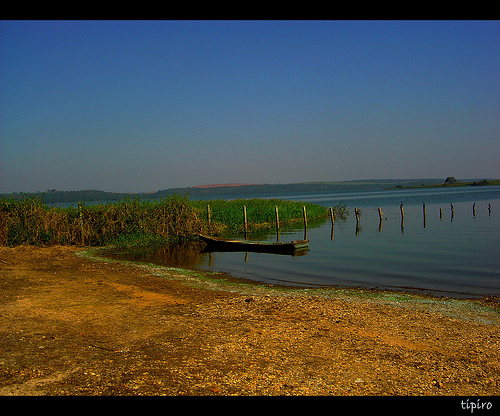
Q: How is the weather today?
A: It is clear.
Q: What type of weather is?
A: It is clear.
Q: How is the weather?
A: It is clear.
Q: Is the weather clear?
A: Yes, it is clear.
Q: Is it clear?
A: Yes, it is clear.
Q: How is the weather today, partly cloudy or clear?
A: It is clear.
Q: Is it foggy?
A: No, it is clear.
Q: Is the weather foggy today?
A: No, it is clear.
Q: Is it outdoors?
A: Yes, it is outdoors.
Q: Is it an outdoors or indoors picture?
A: It is outdoors.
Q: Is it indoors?
A: No, it is outdoors.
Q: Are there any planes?
A: No, there are no planes.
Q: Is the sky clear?
A: Yes, the sky is clear.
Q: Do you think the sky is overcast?
A: No, the sky is clear.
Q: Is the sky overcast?
A: No, the sky is clear.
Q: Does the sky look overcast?
A: No, the sky is clear.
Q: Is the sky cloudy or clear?
A: The sky is clear.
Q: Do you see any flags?
A: No, there are no flags.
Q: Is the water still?
A: Yes, the water is still.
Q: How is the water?
A: The water is still.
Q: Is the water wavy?
A: No, the water is still.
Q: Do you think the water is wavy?
A: No, the water is still.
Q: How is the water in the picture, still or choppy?
A: The water is still.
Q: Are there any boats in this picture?
A: Yes, there is a boat.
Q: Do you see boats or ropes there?
A: Yes, there is a boat.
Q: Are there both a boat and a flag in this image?
A: No, there is a boat but no flags.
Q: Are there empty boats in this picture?
A: Yes, there is an empty boat.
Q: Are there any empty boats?
A: Yes, there is an empty boat.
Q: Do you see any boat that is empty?
A: Yes, there is a boat that is empty.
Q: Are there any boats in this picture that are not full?
A: Yes, there is a empty boat.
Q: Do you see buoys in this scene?
A: No, there are no buoys.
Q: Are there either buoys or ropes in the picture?
A: No, there are no buoys or ropes.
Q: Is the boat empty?
A: Yes, the boat is empty.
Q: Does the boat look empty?
A: Yes, the boat is empty.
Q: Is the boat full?
A: No, the boat is empty.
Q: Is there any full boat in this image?
A: No, there is a boat but it is empty.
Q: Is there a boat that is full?
A: No, there is a boat but it is empty.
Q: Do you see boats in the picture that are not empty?
A: No, there is a boat but it is empty.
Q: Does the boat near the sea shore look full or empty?
A: The boat is empty.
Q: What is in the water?
A: The boat is in the water.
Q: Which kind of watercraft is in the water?
A: The watercraft is a boat.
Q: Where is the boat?
A: The boat is in the water.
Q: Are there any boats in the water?
A: Yes, there is a boat in the water.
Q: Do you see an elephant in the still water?
A: No, there is a boat in the water.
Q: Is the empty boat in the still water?
A: Yes, the boat is in the water.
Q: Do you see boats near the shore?
A: Yes, there is a boat near the shore.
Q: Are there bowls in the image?
A: No, there are no bowls.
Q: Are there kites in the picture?
A: No, there are no kites.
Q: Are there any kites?
A: No, there are no kites.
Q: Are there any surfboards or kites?
A: No, there are no kites or surfboards.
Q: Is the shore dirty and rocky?
A: Yes, the shore is dirty and rocky.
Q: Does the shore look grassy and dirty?
A: No, the shore is dirty but rocky.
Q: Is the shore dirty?
A: Yes, the shore is dirty.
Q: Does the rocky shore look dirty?
A: Yes, the shore is dirty.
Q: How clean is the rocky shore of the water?
A: The shore is dirty.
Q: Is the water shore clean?
A: No, the shore is dirty.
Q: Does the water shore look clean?
A: No, the shore is dirty.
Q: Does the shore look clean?
A: No, the shore is dirty.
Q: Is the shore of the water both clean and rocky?
A: No, the shore is rocky but dirty.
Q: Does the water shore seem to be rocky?
A: Yes, the sea shore is rocky.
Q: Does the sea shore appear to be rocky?
A: Yes, the sea shore is rocky.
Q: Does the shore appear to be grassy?
A: No, the shore is rocky.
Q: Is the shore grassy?
A: No, the shore is rocky.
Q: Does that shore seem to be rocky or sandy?
A: The shore is rocky.